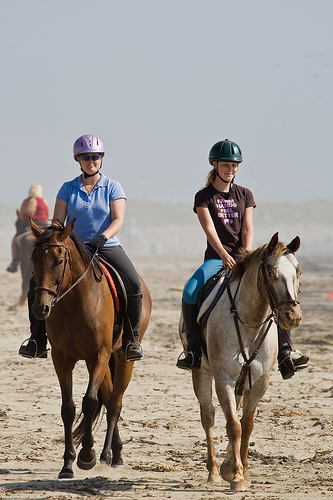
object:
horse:
[178, 231, 304, 491]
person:
[18, 133, 144, 362]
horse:
[28, 218, 152, 478]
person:
[6, 183, 48, 274]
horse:
[5, 207, 50, 305]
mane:
[42, 226, 53, 238]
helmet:
[73, 133, 105, 161]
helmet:
[208, 138, 244, 164]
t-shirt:
[192, 182, 257, 262]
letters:
[212, 195, 239, 226]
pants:
[182, 258, 223, 306]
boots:
[175, 298, 203, 373]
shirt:
[56, 172, 128, 253]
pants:
[92, 245, 144, 336]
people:
[175, 138, 257, 370]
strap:
[79, 166, 103, 178]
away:
[9, 184, 55, 307]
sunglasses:
[75, 152, 104, 163]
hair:
[205, 169, 219, 187]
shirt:
[21, 197, 49, 220]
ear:
[264, 231, 280, 253]